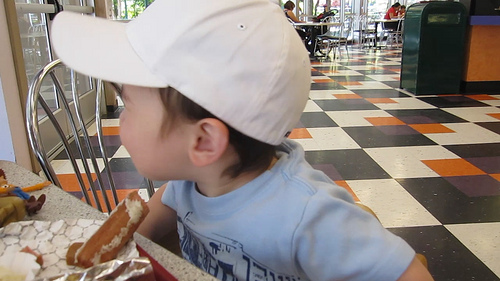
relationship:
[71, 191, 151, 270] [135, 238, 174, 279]
hotdog on tray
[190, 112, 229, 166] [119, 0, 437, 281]
ear of boy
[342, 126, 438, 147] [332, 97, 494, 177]
tile on floor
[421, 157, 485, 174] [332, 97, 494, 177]
tile on floor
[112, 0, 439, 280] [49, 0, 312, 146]
boy wearing baseball cap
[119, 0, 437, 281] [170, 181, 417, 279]
boy wearing a shirt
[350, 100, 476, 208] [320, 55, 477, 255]
tile is on floor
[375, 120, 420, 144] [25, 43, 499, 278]
tile is on floor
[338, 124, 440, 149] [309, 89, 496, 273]
black tile is on floor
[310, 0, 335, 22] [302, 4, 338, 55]
baby is in stroller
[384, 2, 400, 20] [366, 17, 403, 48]
people sits at table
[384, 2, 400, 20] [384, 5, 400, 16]
people wears shirt